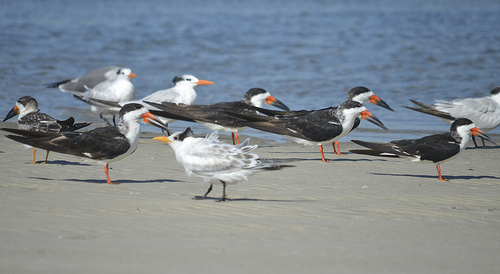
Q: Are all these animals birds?
A: Yes, all the animals are birds.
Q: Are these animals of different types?
A: No, all the animals are birds.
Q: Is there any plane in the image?
A: No, there are no airplanes.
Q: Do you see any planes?
A: No, there are no planes.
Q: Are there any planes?
A: No, there are no planes.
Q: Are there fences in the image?
A: No, there are no fences.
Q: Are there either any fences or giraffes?
A: No, there are no fences or giraffes.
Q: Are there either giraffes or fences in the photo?
A: No, there are no fences or giraffes.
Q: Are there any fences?
A: No, there are no fences.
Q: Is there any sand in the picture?
A: Yes, there is sand.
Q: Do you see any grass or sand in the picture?
A: Yes, there is sand.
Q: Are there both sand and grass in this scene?
A: No, there is sand but no grass.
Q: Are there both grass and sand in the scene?
A: No, there is sand but no grass.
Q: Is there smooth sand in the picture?
A: Yes, there is smooth sand.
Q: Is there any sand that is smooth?
A: Yes, there is sand that is smooth.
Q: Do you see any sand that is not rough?
A: Yes, there is smooth sand.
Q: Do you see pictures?
A: No, there are no pictures.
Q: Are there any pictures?
A: No, there are no pictures.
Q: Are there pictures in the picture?
A: No, there are no pictures.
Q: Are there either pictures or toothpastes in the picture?
A: No, there are no pictures or toothpastes.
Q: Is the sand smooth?
A: Yes, the sand is smooth.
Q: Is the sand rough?
A: No, the sand is smooth.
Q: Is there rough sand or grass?
A: No, there is sand but it is smooth.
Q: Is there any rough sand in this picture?
A: No, there is sand but it is smooth.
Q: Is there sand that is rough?
A: No, there is sand but it is smooth.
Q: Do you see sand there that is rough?
A: No, there is sand but it is smooth.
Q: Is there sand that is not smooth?
A: No, there is sand but it is smooth.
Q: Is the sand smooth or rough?
A: The sand is smooth.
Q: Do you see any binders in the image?
A: No, there are no binders.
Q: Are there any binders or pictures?
A: No, there are no binders or pictures.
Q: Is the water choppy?
A: Yes, the water is choppy.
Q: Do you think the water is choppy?
A: Yes, the water is choppy.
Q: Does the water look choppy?
A: Yes, the water is choppy.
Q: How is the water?
A: The water is choppy.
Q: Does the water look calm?
A: No, the water is choppy.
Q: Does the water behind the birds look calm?
A: No, the water is choppy.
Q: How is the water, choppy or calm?
A: The water is choppy.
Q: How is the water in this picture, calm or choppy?
A: The water is choppy.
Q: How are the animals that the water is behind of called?
A: The animals are birds.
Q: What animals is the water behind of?
A: The water is behind the birds.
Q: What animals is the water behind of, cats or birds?
A: The water is behind birds.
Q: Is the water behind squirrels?
A: No, the water is behind the birds.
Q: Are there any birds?
A: Yes, there are birds.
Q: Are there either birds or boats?
A: Yes, there are birds.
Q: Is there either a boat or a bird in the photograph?
A: Yes, there are birds.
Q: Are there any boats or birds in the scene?
A: Yes, there are birds.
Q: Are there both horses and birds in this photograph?
A: No, there are birds but no horses.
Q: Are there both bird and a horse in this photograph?
A: No, there are birds but no horses.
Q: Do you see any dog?
A: No, there are no dogs.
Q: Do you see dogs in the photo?
A: No, there are no dogs.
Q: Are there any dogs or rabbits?
A: No, there are no dogs or rabbits.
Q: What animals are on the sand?
A: The animals are birds.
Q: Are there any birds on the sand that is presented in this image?
A: Yes, there are birds on the sand.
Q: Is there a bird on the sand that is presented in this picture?
A: Yes, there are birds on the sand.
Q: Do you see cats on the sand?
A: No, there are birds on the sand.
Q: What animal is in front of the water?
A: The birds are in front of the water.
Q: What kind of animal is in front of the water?
A: The animals are birds.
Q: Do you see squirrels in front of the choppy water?
A: No, there are birds in front of the water.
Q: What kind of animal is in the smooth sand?
A: The animals are birds.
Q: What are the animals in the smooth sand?
A: The animals are birds.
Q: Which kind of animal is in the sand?
A: The animals are birds.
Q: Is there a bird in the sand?
A: Yes, there are birds in the sand.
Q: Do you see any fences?
A: No, there are no fences.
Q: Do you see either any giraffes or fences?
A: No, there are no fences or giraffes.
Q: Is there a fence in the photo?
A: No, there are no fences.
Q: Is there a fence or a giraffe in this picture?
A: No, there are no fences or giraffes.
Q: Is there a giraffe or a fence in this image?
A: No, there are no fences or giraffes.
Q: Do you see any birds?
A: Yes, there is a bird.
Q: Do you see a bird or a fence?
A: Yes, there is a bird.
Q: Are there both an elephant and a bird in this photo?
A: No, there is a bird but no elephants.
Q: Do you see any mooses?
A: No, there are no mooses.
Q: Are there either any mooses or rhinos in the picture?
A: No, there are no mooses or rhinos.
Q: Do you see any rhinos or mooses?
A: No, there are no mooses or rhinos.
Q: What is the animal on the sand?
A: The animal is a bird.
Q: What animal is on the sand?
A: The animal is a bird.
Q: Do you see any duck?
A: No, there are no ducks.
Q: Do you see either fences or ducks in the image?
A: No, there are no ducks or fences.